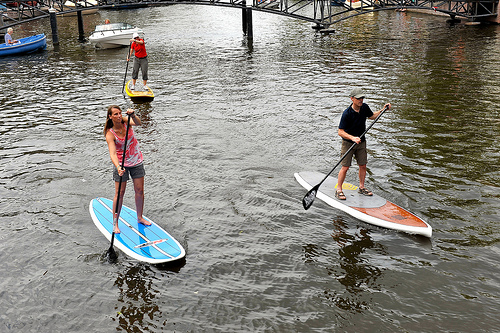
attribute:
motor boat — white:
[90, 20, 150, 52]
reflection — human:
[114, 258, 155, 328]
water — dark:
[1, 2, 497, 332]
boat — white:
[2, 33, 53, 56]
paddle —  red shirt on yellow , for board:
[119, 38, 131, 93]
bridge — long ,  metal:
[4, 0, 495, 31]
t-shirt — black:
[336, 102, 373, 138]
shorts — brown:
[336, 135, 368, 167]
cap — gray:
[347, 87, 368, 101]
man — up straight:
[330, 84, 392, 201]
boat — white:
[85, 17, 152, 61]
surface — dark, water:
[187, 202, 343, 332]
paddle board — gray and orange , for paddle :
[290, 163, 440, 255]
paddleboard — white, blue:
[82, 182, 200, 293]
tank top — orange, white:
[84, 101, 145, 168]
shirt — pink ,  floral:
[106, 120, 143, 170]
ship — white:
[82, 16, 143, 49]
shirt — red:
[128, 44, 148, 55]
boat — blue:
[89, 189, 188, 267]